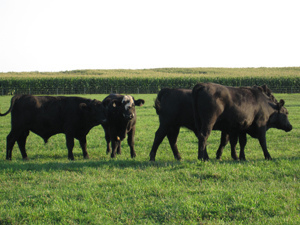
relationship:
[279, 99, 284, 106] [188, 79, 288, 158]
ear of cow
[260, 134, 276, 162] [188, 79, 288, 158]
leg of cow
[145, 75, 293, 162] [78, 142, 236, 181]
cow in field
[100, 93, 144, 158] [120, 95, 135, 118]
black cow with white face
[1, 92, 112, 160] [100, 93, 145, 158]
cow next to black cow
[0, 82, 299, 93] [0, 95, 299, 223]
fence separating grassy area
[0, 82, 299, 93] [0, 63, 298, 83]
fence separating corn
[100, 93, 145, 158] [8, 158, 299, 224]
black cow on grass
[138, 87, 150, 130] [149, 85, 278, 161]
ear of a black cow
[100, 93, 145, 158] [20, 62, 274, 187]
black cow in a pasture